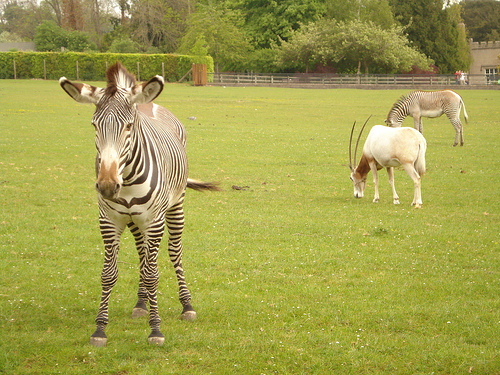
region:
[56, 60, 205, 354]
A black and white zebra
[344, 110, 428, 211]
A white animal eating grass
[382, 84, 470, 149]
A zebra eating grass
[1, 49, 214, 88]
A line of square green bushes.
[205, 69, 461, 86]
A long wooden fence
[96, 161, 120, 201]
A brown snout on a zebra.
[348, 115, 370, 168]
Horns of a white animal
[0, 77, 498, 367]
A field of green grass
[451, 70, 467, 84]
People standing behind a fence.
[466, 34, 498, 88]
A small stone building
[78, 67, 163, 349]
zebra facing the camera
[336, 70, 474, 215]
Ibis and zebra eating grass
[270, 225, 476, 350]
grassy field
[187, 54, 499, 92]
wooden fence keeping the animals in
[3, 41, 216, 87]
hedge making up part of the fence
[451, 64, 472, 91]
people observing the animals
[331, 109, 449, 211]
white goat with very long horns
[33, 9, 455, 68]
heavily wooded area with lots of different trees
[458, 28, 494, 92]
building with a castle like finish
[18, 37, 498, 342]
3 exotic animals in a field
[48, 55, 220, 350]
zebra standing on a grass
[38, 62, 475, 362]
African animals in a grassy field enclosure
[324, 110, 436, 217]
African animal with long horns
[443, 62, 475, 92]
people in the background looking at the animals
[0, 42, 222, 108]
trimmed hedge in the background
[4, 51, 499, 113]
fence in the background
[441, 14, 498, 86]
a tan colored building in the background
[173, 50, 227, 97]
a gate entrance in the background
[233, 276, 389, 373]
small white flowers growing in the grass field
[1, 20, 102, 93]
a man-made structure or building in the background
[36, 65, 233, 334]
Zebra facing the camera.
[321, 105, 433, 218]
Antelope with the zebras.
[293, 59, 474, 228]
The antelope and the zebra in the background are grazing.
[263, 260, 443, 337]
The grass is green.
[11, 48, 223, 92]
The hedges are well manicured.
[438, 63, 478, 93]
People standing behind the fence watching.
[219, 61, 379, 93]
The fence is wooden.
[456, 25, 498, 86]
Building in the background.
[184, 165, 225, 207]
Zebra is wagging it's tail.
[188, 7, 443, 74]
Large group of trees behind the fence.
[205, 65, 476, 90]
Wooden fence for closure.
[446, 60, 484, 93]
Family outing to see animals.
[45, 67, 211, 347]
Zebra showing it's stripes.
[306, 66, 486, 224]
Animals feeding in the sun.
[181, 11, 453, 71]
Large trees to shade.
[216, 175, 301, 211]
Dirt from animals hoofs.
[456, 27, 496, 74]
Animal house for sleep.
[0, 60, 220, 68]
Manicured bushes around the fences.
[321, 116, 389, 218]
Grazing for food to eat.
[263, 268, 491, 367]
Green space for grazing.